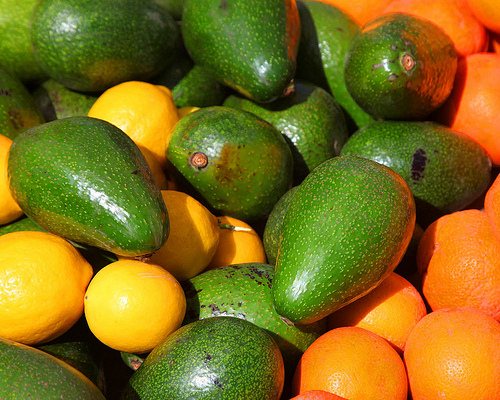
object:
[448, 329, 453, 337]
spotting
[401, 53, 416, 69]
stem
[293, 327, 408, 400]
orange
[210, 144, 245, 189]
bruise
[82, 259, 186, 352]
fruit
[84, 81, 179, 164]
fruit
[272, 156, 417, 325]
avocado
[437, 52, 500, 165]
orange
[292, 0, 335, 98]
shadow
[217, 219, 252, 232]
stem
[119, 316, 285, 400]
peel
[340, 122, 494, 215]
avocado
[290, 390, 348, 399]
top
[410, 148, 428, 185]
blemish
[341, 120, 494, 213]
fruit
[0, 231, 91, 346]
food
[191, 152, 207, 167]
stem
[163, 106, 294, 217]
avocado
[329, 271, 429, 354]
orange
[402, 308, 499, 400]
orange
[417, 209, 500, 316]
orange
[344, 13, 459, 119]
fruit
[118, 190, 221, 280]
lemon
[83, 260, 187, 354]
rind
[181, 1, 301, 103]
avocado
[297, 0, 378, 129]
avocado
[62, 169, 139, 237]
light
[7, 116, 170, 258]
fruit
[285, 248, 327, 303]
light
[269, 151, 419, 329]
fruit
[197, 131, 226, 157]
light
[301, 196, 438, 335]
shadow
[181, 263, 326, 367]
fruit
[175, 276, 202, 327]
shadow